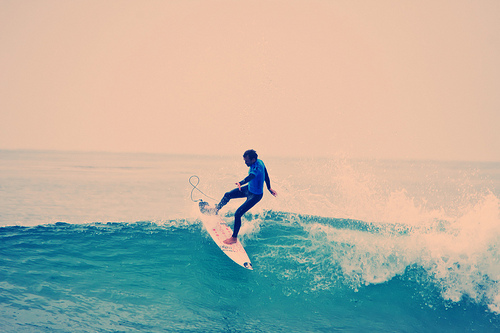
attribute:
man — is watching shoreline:
[209, 143, 281, 253]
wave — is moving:
[3, 212, 495, 329]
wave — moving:
[2, 205, 499, 312]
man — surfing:
[209, 142, 288, 257]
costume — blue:
[214, 163, 312, 240]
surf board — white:
[194, 193, 255, 271]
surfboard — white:
[185, 207, 253, 274]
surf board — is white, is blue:
[197, 199, 254, 271]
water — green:
[33, 206, 255, 327]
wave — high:
[1, 191, 497, 314]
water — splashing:
[0, 151, 498, 328]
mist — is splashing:
[311, 176, 448, 241]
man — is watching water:
[208, 138, 283, 258]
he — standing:
[200, 147, 278, 244]